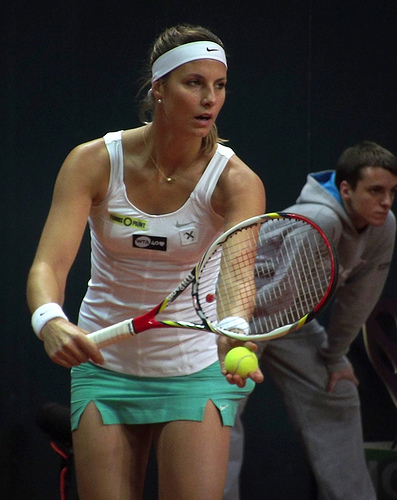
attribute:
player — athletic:
[26, 23, 267, 499]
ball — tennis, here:
[226, 345, 256, 378]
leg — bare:
[155, 416, 228, 499]